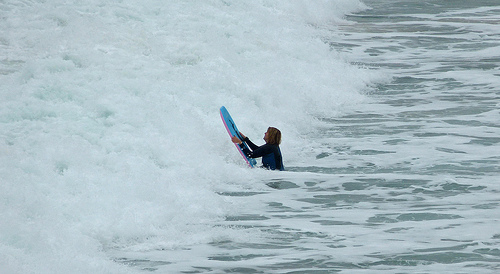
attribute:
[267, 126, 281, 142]
hair — blonde 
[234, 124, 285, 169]
person — getting some exercise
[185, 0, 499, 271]
water — calmer, foamier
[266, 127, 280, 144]
hair — blonde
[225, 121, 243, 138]
design board — black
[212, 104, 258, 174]
board — body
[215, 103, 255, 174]
board — blue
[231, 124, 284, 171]
person — using, enjoying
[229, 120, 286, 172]
person — on their day off, out in the daytime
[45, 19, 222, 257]
wave — large, white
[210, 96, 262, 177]
board — blue